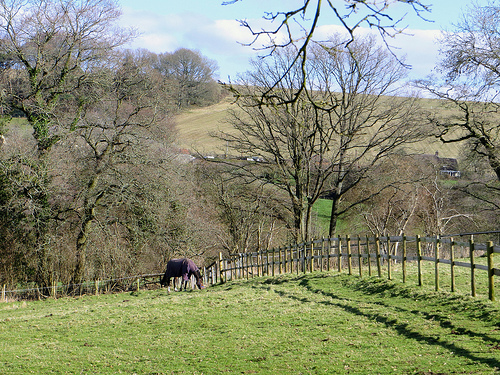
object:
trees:
[386, 76, 499, 224]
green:
[0, 253, 500, 375]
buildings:
[241, 155, 265, 162]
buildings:
[203, 155, 214, 159]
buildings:
[169, 147, 192, 162]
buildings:
[240, 155, 265, 162]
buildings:
[401, 153, 460, 177]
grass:
[0, 254, 500, 375]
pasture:
[0, 241, 500, 375]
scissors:
[412, 154, 462, 172]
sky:
[0, 0, 500, 102]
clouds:
[184, 17, 478, 68]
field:
[0, 1, 500, 375]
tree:
[48, 60, 163, 291]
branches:
[90, 179, 149, 208]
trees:
[152, 48, 221, 111]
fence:
[0, 233, 500, 301]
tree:
[432, 0, 500, 108]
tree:
[218, 0, 434, 115]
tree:
[0, 0, 139, 298]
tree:
[197, 31, 435, 274]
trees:
[204, 43, 343, 274]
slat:
[211, 265, 214, 284]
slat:
[203, 264, 207, 284]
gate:
[205, 260, 219, 285]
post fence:
[118, 274, 149, 290]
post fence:
[408, 233, 500, 300]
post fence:
[315, 234, 392, 279]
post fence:
[223, 248, 265, 282]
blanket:
[167, 258, 205, 294]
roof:
[250, 155, 294, 164]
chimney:
[434, 150, 439, 157]